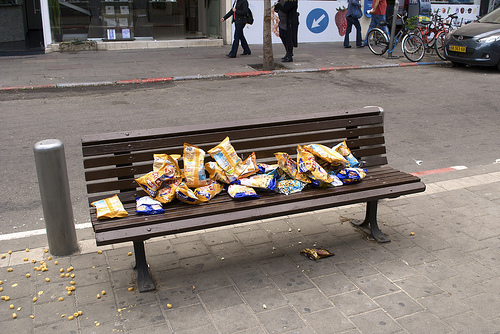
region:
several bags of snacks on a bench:
[78, 109, 434, 248]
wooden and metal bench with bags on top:
[73, 104, 426, 294]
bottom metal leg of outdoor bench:
[124, 240, 166, 297]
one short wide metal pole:
[32, 137, 90, 257]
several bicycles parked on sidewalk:
[365, 16, 447, 73]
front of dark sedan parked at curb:
[445, 7, 499, 69]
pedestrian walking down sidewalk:
[221, 2, 259, 72]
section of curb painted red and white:
[5, 57, 452, 99]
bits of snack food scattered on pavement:
[1, 244, 133, 327]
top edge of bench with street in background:
[71, 97, 391, 140]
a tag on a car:
[446, 36, 468, 66]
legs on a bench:
[121, 235, 166, 297]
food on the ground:
[26, 243, 82, 315]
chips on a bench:
[127, 158, 195, 216]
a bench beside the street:
[76, 121, 148, 277]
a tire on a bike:
[403, 31, 421, 64]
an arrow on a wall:
[306, 8, 331, 37]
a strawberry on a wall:
[334, 9, 350, 41]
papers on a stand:
[96, 9, 145, 44]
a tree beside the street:
[256, 15, 288, 80]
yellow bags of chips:
[90, 142, 389, 211]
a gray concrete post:
[29, 136, 78, 260]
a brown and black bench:
[82, 103, 422, 294]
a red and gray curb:
[9, 59, 436, 93]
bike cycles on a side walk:
[369, 7, 455, 64]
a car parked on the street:
[442, 7, 499, 70]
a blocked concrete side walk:
[336, 246, 480, 324]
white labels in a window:
[97, 3, 135, 45]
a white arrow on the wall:
[303, 7, 333, 38]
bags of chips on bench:
[88, 131, 362, 216]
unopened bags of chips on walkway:
[102, 136, 290, 234]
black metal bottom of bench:
[124, 242, 168, 296]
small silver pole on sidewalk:
[31, 133, 76, 275]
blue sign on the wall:
[305, 6, 332, 44]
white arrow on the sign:
[305, 11, 327, 32]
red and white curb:
[0, 76, 187, 101]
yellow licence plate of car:
[444, 36, 475, 54]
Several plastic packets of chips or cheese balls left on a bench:
[90, 133, 365, 218]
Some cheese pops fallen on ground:
[0, 246, 132, 326]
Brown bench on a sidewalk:
[80, 105, 425, 290]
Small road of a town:
[0, 65, 495, 250]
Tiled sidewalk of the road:
[0, 162, 497, 328]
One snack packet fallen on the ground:
[298, 245, 329, 256]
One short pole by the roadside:
[31, 138, 78, 255]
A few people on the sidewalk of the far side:
[219, 0, 386, 62]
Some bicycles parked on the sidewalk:
[366, 10, 478, 61]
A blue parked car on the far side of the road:
[443, 5, 498, 65]